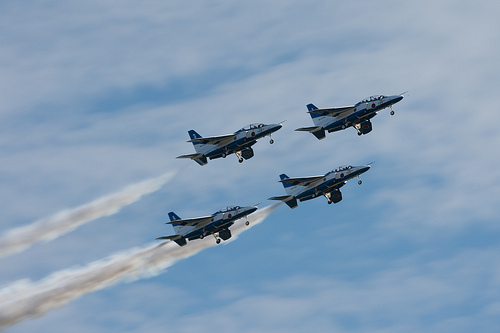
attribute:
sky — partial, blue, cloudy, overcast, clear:
[5, 4, 488, 332]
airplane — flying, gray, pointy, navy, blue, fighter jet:
[185, 117, 280, 163]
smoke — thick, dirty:
[1, 160, 176, 261]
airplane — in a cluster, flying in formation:
[274, 164, 367, 209]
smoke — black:
[111, 208, 284, 288]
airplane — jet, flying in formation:
[163, 205, 254, 249]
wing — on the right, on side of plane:
[187, 132, 234, 147]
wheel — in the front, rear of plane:
[232, 146, 248, 165]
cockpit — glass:
[238, 120, 264, 136]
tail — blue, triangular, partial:
[188, 129, 208, 152]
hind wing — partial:
[176, 150, 198, 161]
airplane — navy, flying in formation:
[300, 91, 403, 143]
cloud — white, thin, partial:
[1, 4, 497, 164]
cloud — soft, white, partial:
[2, 142, 487, 329]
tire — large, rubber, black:
[268, 138, 275, 146]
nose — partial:
[266, 123, 283, 136]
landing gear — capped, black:
[240, 146, 257, 161]